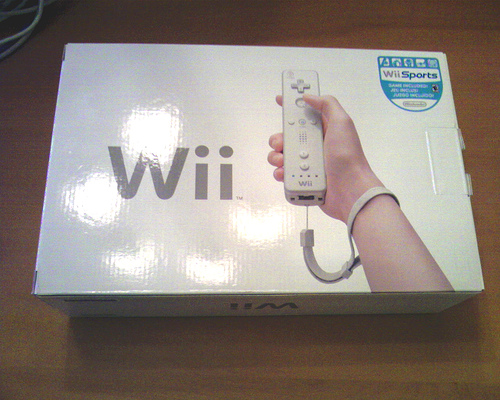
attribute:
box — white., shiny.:
[29, 40, 485, 318]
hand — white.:
[266, 94, 382, 222]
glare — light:
[119, 108, 179, 159]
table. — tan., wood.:
[1, 0, 499, 400]